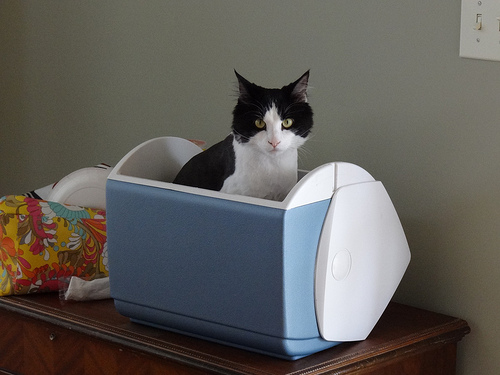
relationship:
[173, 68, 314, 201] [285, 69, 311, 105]
cat has an ear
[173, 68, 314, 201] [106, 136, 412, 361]
cat in cooler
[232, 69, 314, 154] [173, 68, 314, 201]
head on cat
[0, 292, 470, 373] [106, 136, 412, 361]
table under cooler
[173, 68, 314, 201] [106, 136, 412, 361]
cat sitting in cooler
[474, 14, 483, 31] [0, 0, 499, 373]
light switch on wall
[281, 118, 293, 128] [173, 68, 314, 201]
eye on cat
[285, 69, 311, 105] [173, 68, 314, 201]
ear on cat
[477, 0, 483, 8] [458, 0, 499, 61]
screw on light plate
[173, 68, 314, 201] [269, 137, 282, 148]
cat has a nose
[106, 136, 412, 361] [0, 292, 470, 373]
cooler on table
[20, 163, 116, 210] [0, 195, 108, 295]
items sticking out of bag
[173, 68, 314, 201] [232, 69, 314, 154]
cat has a head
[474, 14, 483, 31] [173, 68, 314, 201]
light switch next to cat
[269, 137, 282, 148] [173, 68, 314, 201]
nose on cat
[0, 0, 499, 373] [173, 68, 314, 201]
wall behind cat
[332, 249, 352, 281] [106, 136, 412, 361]
circle on cooler